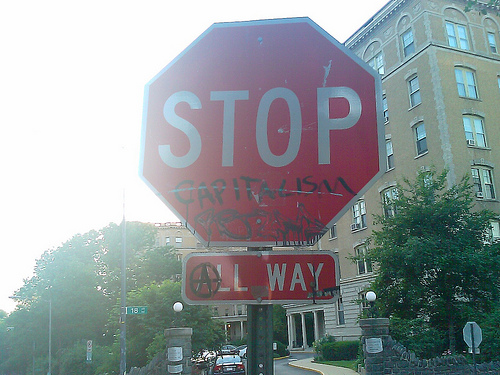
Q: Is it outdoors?
A: Yes, it is outdoors.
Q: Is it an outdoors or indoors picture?
A: It is outdoors.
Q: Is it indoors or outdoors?
A: It is outdoors.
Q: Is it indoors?
A: No, it is outdoors.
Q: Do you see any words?
A: Yes, there are words.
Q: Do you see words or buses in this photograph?
A: Yes, there are words.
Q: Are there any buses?
A: No, there are no buses.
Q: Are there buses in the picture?
A: No, there are no buses.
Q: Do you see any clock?
A: No, there are no clocks.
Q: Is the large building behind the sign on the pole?
A: Yes, the building is behind the sign.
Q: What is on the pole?
A: The sign is on the pole.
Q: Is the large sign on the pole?
A: Yes, the sign is on the pole.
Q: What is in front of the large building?
A: The sign is in front of the building.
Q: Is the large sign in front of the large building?
A: Yes, the sign is in front of the building.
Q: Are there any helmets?
A: No, there are no helmets.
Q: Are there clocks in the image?
A: No, there are no clocks.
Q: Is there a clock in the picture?
A: No, there are no clocks.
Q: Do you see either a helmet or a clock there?
A: No, there are no clocks or helmets.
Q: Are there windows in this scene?
A: Yes, there is a window.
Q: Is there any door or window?
A: Yes, there is a window.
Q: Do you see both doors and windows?
A: No, there is a window but no doors.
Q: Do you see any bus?
A: No, there are no buses.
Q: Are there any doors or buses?
A: No, there are no buses or doors.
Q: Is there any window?
A: Yes, there is a window.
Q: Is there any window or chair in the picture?
A: Yes, there is a window.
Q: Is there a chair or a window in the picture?
A: Yes, there is a window.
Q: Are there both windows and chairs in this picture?
A: No, there is a window but no chairs.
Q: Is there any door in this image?
A: No, there are no doors.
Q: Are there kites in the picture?
A: No, there are no kites.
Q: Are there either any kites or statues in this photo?
A: No, there are no kites or statues.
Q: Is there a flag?
A: No, there are no flags.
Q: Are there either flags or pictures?
A: No, there are no flags or pictures.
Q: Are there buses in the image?
A: No, there are no buses.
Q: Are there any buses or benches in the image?
A: No, there are no buses or benches.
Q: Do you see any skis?
A: No, there are no skis.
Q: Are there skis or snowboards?
A: No, there are no skis or snowboards.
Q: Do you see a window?
A: Yes, there is a window.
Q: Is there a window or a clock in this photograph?
A: Yes, there is a window.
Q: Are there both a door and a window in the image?
A: No, there is a window but no doors.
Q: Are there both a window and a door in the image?
A: No, there is a window but no doors.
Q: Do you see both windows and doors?
A: No, there is a window but no doors.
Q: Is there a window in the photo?
A: Yes, there is a window.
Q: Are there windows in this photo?
A: Yes, there is a window.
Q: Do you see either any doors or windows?
A: Yes, there is a window.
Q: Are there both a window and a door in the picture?
A: No, there is a window but no doors.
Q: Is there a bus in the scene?
A: No, there are no buses.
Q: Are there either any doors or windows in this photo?
A: Yes, there is a window.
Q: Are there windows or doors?
A: Yes, there is a window.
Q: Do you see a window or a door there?
A: Yes, there is a window.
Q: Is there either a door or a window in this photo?
A: Yes, there is a window.